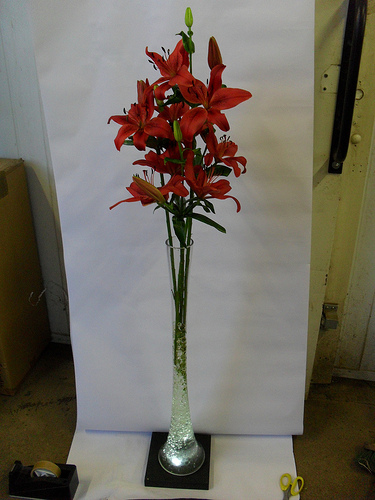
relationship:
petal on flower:
[111, 120, 138, 151] [106, 96, 177, 309]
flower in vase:
[142, 38, 197, 101] [144, 235, 212, 491]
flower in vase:
[175, 61, 255, 137] [144, 235, 212, 491]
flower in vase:
[182, 149, 242, 212] [144, 235, 212, 491]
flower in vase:
[199, 132, 252, 180] [144, 235, 212, 491]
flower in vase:
[108, 97, 180, 157] [144, 235, 212, 491]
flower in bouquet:
[175, 61, 255, 137] [100, 1, 259, 244]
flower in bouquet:
[199, 132, 252, 180] [100, 1, 259, 244]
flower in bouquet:
[106, 169, 194, 211] [100, 1, 259, 244]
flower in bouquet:
[108, 97, 180, 157] [100, 1, 259, 244]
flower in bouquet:
[142, 38, 197, 101] [100, 1, 259, 244]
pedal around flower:
[209, 87, 251, 110] [108, 5, 252, 474]